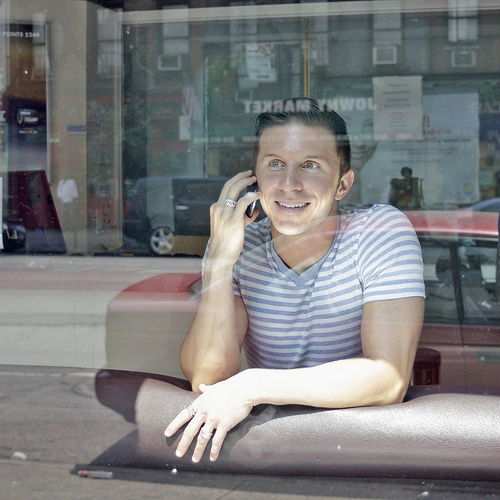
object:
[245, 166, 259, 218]
cell phone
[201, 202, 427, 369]
shirt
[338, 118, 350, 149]
hair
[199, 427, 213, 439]
ring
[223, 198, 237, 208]
ring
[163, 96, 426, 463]
he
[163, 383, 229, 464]
fingers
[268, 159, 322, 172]
eyes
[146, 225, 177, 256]
tire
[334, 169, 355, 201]
ear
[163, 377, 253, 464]
hand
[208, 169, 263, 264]
hand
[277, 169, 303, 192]
nose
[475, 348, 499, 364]
handle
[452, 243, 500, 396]
door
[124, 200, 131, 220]
light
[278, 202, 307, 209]
teeth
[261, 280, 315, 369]
stripes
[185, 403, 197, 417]
ring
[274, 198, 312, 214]
mouth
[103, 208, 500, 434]
car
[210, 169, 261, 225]
fingers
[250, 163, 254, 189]
ear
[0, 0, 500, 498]
window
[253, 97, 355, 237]
man's head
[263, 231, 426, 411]
man's arm